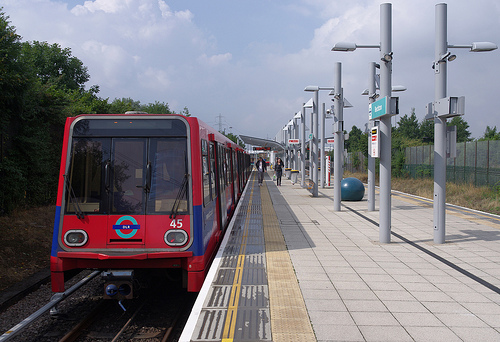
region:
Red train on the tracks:
[38, 99, 250, 290]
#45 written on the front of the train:
[161, 214, 196, 232]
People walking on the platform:
[257, 153, 290, 184]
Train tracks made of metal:
[11, 283, 181, 335]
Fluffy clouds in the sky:
[19, 8, 488, 152]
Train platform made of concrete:
[260, 151, 491, 336]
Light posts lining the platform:
[272, 77, 452, 249]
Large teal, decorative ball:
[333, 173, 373, 205]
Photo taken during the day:
[4, 0, 496, 332]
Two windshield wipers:
[40, 165, 209, 230]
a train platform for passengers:
[52, 37, 462, 320]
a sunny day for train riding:
[30, 42, 363, 261]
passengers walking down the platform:
[251, 142, 301, 192]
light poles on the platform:
[274, 48, 499, 234]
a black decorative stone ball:
[328, 168, 390, 212]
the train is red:
[40, 96, 265, 294]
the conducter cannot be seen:
[65, 122, 193, 225]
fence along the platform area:
[394, 123, 499, 210]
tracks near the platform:
[5, 263, 216, 340]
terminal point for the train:
[234, 126, 294, 158]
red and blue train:
[48, 114, 223, 289]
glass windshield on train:
[74, 129, 182, 214]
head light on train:
[166, 229, 186, 245]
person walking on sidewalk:
[256, 156, 266, 181]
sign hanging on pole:
[368, 128, 380, 158]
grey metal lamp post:
[380, 4, 392, 240]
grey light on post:
[332, 41, 382, 51]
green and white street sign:
[366, 99, 388, 116]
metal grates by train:
[191, 155, 274, 339]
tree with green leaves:
[2, 11, 64, 206]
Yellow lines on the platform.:
[224, 177, 260, 339]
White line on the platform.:
[181, 263, 221, 322]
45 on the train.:
[151, 212, 199, 238]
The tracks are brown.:
[76, 315, 169, 340]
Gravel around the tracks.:
[39, 293, 152, 332]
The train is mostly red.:
[61, 114, 232, 268]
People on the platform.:
[253, 147, 297, 192]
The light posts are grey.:
[296, 33, 481, 219]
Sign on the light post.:
[347, 83, 416, 140]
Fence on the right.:
[412, 133, 499, 195]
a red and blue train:
[51, 108, 250, 313]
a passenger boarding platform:
[178, 156, 497, 338]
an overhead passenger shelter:
[238, 131, 280, 149]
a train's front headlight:
[63, 230, 85, 245]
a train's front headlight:
[163, 225, 187, 247]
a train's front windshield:
[70, 129, 183, 214]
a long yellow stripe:
[215, 164, 255, 339]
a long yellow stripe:
[256, 173, 316, 338]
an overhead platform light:
[326, 38, 384, 55]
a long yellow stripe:
[446, 37, 498, 54]